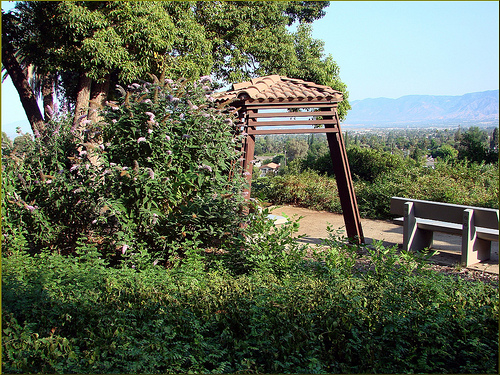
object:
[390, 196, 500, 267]
bench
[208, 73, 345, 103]
canopy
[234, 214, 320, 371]
bushes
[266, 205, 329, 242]
floor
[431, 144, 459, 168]
trees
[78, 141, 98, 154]
flowers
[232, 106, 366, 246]
structure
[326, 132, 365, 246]
pillar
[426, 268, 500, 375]
bush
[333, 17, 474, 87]
sky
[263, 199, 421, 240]
land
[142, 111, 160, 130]
flowers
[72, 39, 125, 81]
branches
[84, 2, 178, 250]
trees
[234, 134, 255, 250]
legs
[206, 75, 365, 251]
pergola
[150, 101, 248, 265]
bush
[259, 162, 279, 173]
house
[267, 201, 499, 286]
sidewalk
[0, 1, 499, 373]
garden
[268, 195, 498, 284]
path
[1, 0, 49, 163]
plants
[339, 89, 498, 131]
mountain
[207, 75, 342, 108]
roof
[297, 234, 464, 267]
shadow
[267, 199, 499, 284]
ground